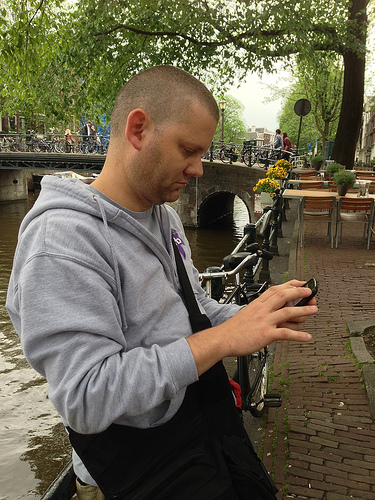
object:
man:
[5, 64, 318, 496]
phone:
[281, 277, 318, 309]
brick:
[287, 484, 321, 497]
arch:
[197, 190, 252, 228]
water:
[183, 195, 249, 273]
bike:
[198, 241, 284, 420]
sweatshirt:
[4, 170, 248, 436]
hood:
[16, 169, 121, 248]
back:
[300, 196, 336, 210]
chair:
[300, 196, 336, 249]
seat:
[222, 250, 260, 270]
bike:
[218, 138, 258, 167]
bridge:
[0, 129, 284, 229]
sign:
[294, 98, 312, 116]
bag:
[64, 228, 279, 499]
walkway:
[241, 210, 373, 497]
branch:
[57, 0, 343, 123]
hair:
[110, 64, 220, 141]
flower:
[252, 177, 281, 197]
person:
[271, 129, 284, 164]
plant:
[332, 169, 356, 185]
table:
[281, 188, 373, 242]